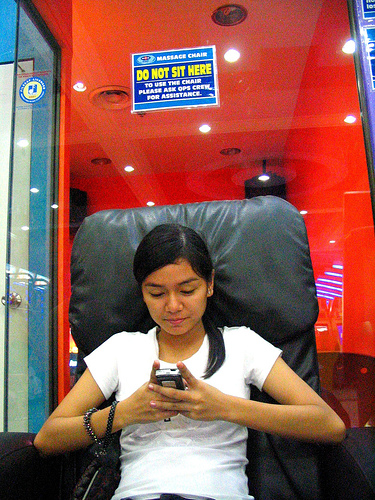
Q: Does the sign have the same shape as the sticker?
A: No, the sticker is round and the sign is square.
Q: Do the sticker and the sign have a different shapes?
A: Yes, the sticker is round and the sign is square.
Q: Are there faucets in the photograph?
A: No, there are no faucets.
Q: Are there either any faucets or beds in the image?
A: No, there are no faucets or beds.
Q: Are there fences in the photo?
A: No, there are no fences.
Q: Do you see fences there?
A: No, there are no fences.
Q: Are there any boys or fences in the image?
A: No, there are no fences or boys.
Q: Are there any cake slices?
A: No, there are no cake slices.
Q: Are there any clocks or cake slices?
A: No, there are no cake slices or clocks.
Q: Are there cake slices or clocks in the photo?
A: No, there are no cake slices or clocks.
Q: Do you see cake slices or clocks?
A: No, there are no cake slices or clocks.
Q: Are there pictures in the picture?
A: No, there are no pictures.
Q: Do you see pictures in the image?
A: No, there are no pictures.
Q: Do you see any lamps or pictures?
A: No, there are no pictures or lamps.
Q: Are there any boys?
A: No, there are no boys.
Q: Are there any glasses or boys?
A: No, there are no boys or glasses.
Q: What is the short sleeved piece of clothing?
A: The clothing item is a shirt.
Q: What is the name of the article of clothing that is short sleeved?
A: The clothing item is a shirt.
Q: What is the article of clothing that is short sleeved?
A: The clothing item is a shirt.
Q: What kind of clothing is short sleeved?
A: The clothing is a shirt.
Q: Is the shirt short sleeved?
A: Yes, the shirt is short sleeved.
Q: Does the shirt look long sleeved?
A: No, the shirt is short sleeved.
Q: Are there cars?
A: No, there are no cars.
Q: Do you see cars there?
A: No, there are no cars.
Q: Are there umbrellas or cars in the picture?
A: No, there are no cars or umbrellas.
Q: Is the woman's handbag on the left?
A: Yes, the handbag is on the left of the image.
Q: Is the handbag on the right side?
A: No, the handbag is on the left of the image.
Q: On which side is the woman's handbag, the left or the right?
A: The handbag is on the left of the image.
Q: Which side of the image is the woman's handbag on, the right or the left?
A: The handbag is on the left of the image.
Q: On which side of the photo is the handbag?
A: The handbag is on the left of the image.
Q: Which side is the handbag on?
A: The handbag is on the left of the image.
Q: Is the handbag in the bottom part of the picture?
A: Yes, the handbag is in the bottom of the image.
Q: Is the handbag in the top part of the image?
A: No, the handbag is in the bottom of the image.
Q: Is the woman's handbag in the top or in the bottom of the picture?
A: The handbag is in the bottom of the image.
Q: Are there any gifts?
A: No, there are no gifts.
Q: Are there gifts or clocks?
A: No, there are no gifts or clocks.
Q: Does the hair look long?
A: Yes, the hair is long.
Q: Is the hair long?
A: Yes, the hair is long.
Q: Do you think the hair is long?
A: Yes, the hair is long.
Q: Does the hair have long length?
A: Yes, the hair is long.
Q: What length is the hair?
A: The hair is long.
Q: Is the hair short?
A: No, the hair is long.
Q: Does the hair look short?
A: No, the hair is long.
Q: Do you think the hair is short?
A: No, the hair is long.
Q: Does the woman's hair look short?
A: No, the hair is long.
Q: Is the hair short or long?
A: The hair is long.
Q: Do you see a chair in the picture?
A: Yes, there is a chair.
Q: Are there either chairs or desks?
A: Yes, there is a chair.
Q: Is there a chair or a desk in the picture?
A: Yes, there is a chair.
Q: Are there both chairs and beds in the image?
A: No, there is a chair but no beds.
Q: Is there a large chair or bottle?
A: Yes, there is a large chair.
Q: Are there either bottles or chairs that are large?
A: Yes, the chair is large.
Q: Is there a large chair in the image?
A: Yes, there is a large chair.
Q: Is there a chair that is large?
A: Yes, there is a chair that is large.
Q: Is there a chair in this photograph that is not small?
A: Yes, there is a large chair.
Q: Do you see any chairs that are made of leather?
A: Yes, there is a chair that is made of leather.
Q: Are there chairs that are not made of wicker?
A: Yes, there is a chair that is made of leather.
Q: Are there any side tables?
A: No, there are no side tables.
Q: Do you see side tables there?
A: No, there are no side tables.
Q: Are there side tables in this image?
A: No, there are no side tables.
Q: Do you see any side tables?
A: No, there are no side tables.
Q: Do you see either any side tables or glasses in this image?
A: No, there are no side tables or glasses.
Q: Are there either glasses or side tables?
A: No, there are no side tables or glasses.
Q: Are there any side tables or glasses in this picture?
A: No, there are no side tables or glasses.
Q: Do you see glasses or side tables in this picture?
A: No, there are no side tables or glasses.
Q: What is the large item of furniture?
A: The piece of furniture is a chair.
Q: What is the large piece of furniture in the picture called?
A: The piece of furniture is a chair.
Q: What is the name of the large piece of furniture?
A: The piece of furniture is a chair.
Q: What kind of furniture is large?
A: The furniture is a chair.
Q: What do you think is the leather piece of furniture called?
A: The piece of furniture is a chair.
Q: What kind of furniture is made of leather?
A: The furniture is a chair.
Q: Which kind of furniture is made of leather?
A: The furniture is a chair.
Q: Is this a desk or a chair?
A: This is a chair.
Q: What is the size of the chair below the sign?
A: The chair is large.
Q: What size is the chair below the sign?
A: The chair is large.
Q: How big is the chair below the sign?
A: The chair is large.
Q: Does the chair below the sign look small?
A: No, the chair is large.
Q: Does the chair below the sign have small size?
A: No, the chair is large.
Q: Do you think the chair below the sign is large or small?
A: The chair is large.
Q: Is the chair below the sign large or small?
A: The chair is large.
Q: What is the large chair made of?
A: The chair is made of leather.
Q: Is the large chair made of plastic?
A: No, the chair is made of leather.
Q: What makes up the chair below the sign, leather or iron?
A: The chair is made of leather.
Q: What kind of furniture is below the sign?
A: The piece of furniture is a chair.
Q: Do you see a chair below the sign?
A: Yes, there is a chair below the sign.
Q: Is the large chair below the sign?
A: Yes, the chair is below the sign.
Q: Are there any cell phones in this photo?
A: Yes, there is a cell phone.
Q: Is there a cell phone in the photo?
A: Yes, there is a cell phone.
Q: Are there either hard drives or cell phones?
A: Yes, there is a cell phone.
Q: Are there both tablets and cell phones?
A: No, there is a cell phone but no tablets.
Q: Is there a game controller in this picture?
A: No, there are no game controllers.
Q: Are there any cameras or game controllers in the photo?
A: No, there are no game controllers or cameras.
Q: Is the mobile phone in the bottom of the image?
A: Yes, the mobile phone is in the bottom of the image.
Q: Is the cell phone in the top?
A: No, the cell phone is in the bottom of the image.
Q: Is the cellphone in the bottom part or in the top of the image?
A: The cellphone is in the bottom of the image.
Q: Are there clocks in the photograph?
A: No, there are no clocks.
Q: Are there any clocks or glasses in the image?
A: No, there are no clocks or glasses.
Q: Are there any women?
A: Yes, there is a woman.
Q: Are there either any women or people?
A: Yes, there is a woman.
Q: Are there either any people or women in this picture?
A: Yes, there is a woman.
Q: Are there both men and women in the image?
A: No, there is a woman but no men.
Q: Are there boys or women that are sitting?
A: Yes, the woman is sitting.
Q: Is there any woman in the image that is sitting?
A: Yes, there is a woman that is sitting.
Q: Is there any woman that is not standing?
A: Yes, there is a woman that is sitting.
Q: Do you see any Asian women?
A: Yes, there is an Asian woman.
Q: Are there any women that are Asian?
A: Yes, there is a woman that is asian.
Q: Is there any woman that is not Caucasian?
A: Yes, there is a Asian woman.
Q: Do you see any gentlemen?
A: No, there are no gentlemen.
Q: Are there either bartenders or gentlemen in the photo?
A: No, there are no gentlemen or bartenders.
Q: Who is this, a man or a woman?
A: This is a woman.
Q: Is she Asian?
A: Yes, the woman is asian.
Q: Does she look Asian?
A: Yes, the woman is asian.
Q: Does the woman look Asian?
A: Yes, the woman is asian.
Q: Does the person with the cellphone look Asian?
A: Yes, the woman is asian.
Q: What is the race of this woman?
A: The woman is asian.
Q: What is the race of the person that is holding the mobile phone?
A: The woman is asian.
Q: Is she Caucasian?
A: No, the woman is asian.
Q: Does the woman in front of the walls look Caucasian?
A: No, the woman is asian.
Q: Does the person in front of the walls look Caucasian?
A: No, the woman is asian.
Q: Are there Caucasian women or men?
A: No, there is a woman but she is asian.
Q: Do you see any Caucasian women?
A: No, there is a woman but she is asian.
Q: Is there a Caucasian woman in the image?
A: No, there is a woman but she is asian.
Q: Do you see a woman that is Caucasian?
A: No, there is a woman but she is asian.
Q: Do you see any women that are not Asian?
A: No, there is a woman but she is asian.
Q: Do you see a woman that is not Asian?
A: No, there is a woman but she is asian.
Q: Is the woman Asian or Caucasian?
A: The woman is asian.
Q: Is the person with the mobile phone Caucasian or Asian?
A: The woman is asian.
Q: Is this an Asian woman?
A: Yes, this is an Asian woman.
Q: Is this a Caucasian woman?
A: No, this is an Asian woman.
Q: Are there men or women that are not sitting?
A: No, there is a woman but she is sitting.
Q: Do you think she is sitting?
A: Yes, the woman is sitting.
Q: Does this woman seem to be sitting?
A: Yes, the woman is sitting.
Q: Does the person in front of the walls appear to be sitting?
A: Yes, the woman is sitting.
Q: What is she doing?
A: The woman is sitting.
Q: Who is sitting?
A: The woman is sitting.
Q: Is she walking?
A: No, the woman is sitting.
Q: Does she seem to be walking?
A: No, the woman is sitting.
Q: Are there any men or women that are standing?
A: No, there is a woman but she is sitting.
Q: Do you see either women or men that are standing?
A: No, there is a woman but she is sitting.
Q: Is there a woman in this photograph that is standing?
A: No, there is a woman but she is sitting.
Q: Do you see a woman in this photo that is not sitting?
A: No, there is a woman but she is sitting.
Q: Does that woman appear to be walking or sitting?
A: The woman is sitting.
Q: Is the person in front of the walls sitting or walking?
A: The woman is sitting.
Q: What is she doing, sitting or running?
A: The woman is sitting.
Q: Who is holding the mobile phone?
A: The woman is holding the mobile phone.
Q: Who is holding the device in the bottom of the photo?
A: The woman is holding the mobile phone.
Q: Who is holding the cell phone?
A: The woman is holding the mobile phone.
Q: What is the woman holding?
A: The woman is holding the mobile phone.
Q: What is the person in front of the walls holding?
A: The woman is holding the mobile phone.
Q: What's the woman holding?
A: The woman is holding the mobile phone.